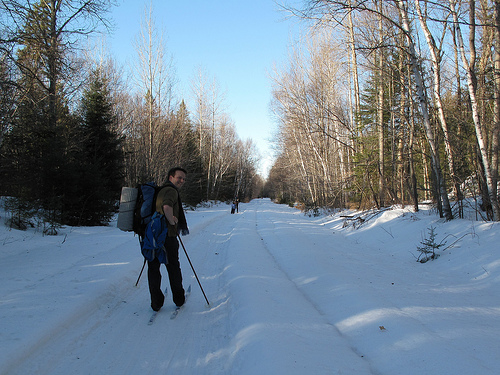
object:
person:
[138, 166, 189, 314]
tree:
[135, 0, 164, 187]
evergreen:
[68, 71, 129, 227]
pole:
[175, 234, 210, 306]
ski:
[168, 284, 193, 322]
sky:
[0, 0, 499, 184]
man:
[229, 195, 240, 216]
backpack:
[128, 182, 181, 237]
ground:
[0, 197, 497, 372]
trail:
[74, 234, 211, 375]